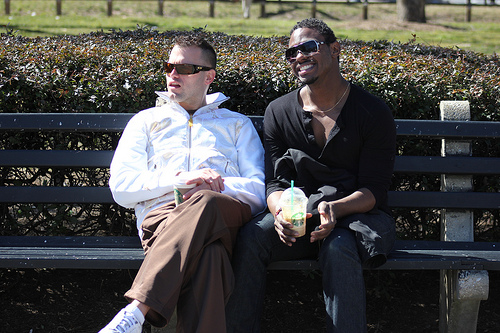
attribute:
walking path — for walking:
[0, 1, 498, 21]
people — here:
[98, 18, 395, 332]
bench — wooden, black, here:
[0, 101, 498, 332]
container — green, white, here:
[279, 179, 308, 237]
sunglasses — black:
[285, 39, 331, 61]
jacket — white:
[110, 92, 266, 230]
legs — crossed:
[96, 190, 251, 332]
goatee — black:
[300, 77, 316, 84]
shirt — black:
[263, 84, 396, 216]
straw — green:
[289, 178, 294, 213]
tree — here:
[396, 1, 426, 23]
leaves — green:
[5, 43, 135, 101]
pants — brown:
[124, 188, 253, 333]